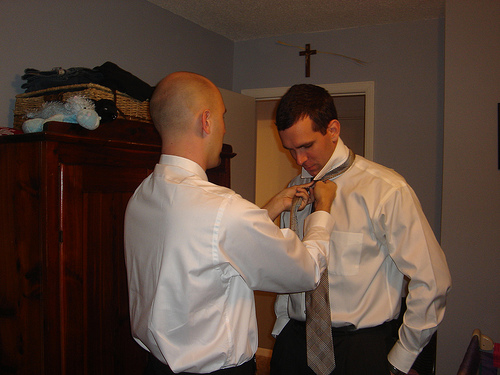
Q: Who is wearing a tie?
A: The men.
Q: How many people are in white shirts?
A: Two.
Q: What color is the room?
A: Blue.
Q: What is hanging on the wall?
A: Cross.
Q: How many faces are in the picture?
A: One.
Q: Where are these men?
A: Bedroom.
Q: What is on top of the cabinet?
A: Basket.